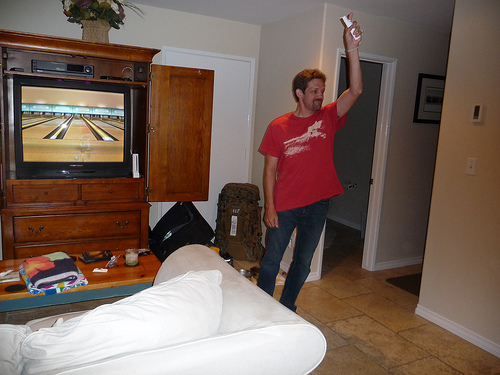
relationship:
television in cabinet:
[10, 75, 145, 180] [2, 30, 224, 274]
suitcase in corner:
[202, 175, 277, 273] [222, 2, 294, 273]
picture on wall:
[410, 71, 450, 131] [294, 5, 457, 284]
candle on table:
[121, 247, 141, 268] [4, 205, 220, 330]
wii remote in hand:
[338, 13, 363, 44] [339, 10, 363, 55]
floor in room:
[0, 271, 497, 373] [1, 3, 498, 373]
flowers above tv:
[55, 0, 134, 19] [7, 68, 127, 179]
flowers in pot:
[55, 0, 134, 19] [70, 10, 117, 42]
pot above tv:
[70, 10, 117, 42] [7, 68, 127, 179]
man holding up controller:
[256, 8, 369, 310] [339, 15, 360, 39]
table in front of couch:
[0, 241, 163, 318] [0, 242, 336, 374]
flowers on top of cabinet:
[60, 0, 135, 42] [2, 27, 212, 252]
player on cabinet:
[25, 55, 99, 80] [3, 44, 170, 92]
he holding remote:
[269, 67, 335, 309] [336, 10, 364, 40]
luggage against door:
[208, 160, 285, 271] [161, 51, 260, 240]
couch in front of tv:
[0, 242, 336, 374] [1, 71, 144, 183]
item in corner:
[212, 181, 263, 260] [402, 267, 459, 347]